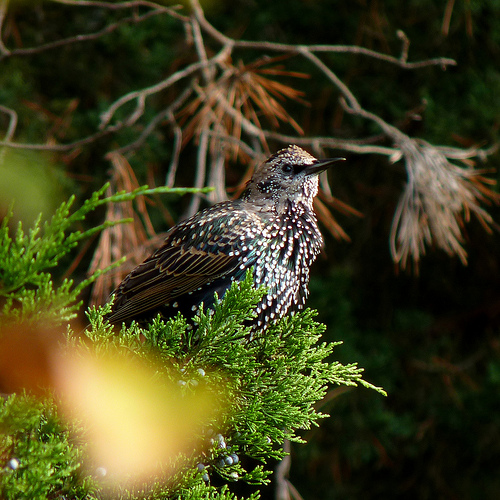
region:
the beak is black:
[305, 137, 352, 187]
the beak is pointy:
[303, 143, 365, 171]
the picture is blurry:
[10, 306, 245, 492]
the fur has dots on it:
[205, 195, 308, 282]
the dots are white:
[177, 181, 332, 321]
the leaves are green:
[164, 283, 355, 476]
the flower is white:
[369, 107, 471, 270]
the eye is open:
[272, 155, 299, 181]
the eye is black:
[261, 152, 301, 180]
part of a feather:
[217, 305, 237, 345]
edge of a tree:
[247, 435, 265, 473]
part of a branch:
[268, 374, 278, 382]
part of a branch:
[377, 382, 382, 407]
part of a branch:
[373, 403, 383, 413]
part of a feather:
[186, 304, 204, 329]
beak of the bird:
[305, 140, 361, 185]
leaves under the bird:
[241, 325, 341, 407]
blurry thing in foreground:
[30, 325, 215, 450]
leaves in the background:
[345, 320, 466, 425]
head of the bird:
[242, 125, 352, 205]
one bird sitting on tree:
[116, 95, 398, 320]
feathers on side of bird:
[90, 197, 255, 317]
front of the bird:
[246, 192, 333, 303]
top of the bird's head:
[248, 131, 313, 163]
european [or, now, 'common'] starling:
[64, 134, 356, 369]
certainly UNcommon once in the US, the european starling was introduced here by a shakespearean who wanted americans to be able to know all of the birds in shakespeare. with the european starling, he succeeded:
[75, 132, 357, 364]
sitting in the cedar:
[0, 165, 395, 498]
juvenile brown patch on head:
[250, 132, 316, 174]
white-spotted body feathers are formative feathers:
[123, 196, 341, 351]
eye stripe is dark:
[275, 158, 307, 183]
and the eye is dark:
[278, 161, 293, 176]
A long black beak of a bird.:
[307, 152, 344, 174]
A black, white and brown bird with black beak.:
[107, 143, 347, 338]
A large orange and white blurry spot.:
[1, 322, 227, 496]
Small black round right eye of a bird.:
[282, 164, 292, 174]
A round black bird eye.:
[282, 164, 292, 176]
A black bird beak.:
[305, 154, 346, 173]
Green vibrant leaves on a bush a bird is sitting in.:
[1, 185, 388, 497]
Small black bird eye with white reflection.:
[282, 163, 292, 174]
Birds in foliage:
[90, 138, 353, 342]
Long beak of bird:
[282, 150, 352, 184]